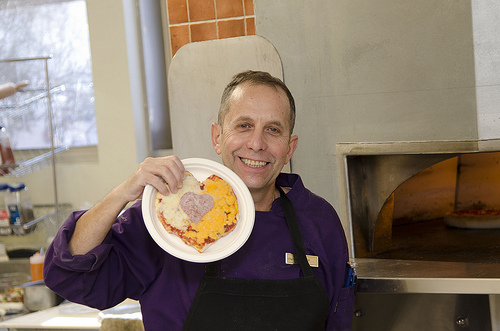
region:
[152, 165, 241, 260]
heart shaped food in middle of plate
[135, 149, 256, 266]
paper plate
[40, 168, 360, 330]
purple chefs coat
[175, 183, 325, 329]
black apron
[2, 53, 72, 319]
metal shelves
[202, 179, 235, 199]
cheese on top of food item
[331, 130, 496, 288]
painting on wall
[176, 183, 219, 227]
heart shaped slice of meat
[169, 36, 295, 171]
a rectangular pizza board behind the chef's head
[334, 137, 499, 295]
a very hot pizza oven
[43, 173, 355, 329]
a purple chef's jacket being worn by the chef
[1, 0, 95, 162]
a window on the back wall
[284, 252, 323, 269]
a white name tag on the chef's purple jacket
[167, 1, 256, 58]
tiles on the wall behind the pizza paddle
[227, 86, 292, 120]
the chef's high forehead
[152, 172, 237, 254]
a heart shaped pizza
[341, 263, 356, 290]
blue ink pens in the chef's pocket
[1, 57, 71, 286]
a medal rack for spices and rolling pins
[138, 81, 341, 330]
a man holding up a heart shaped pizza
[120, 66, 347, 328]
a man wearing a black apron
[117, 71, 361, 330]
a man holding up a plate of food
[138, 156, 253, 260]
heart shaped pizza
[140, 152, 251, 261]
heart shaped pizza with heart shaped meat in the middle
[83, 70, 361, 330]
a man wearing a gold name tag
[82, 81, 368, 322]
a man holding a heart shaped pizza on a plate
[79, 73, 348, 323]
a smiling man holding up a heart shaped pizza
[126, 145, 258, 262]
man holding a Pizza shaped like a heart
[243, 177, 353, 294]
man with a purple shirt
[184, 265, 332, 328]
man wearing a black apron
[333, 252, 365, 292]
pen on the side of the jacket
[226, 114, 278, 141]
man with blue eyes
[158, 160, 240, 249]
cheese pizza on a plate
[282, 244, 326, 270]
name tag on a shirt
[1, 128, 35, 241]
spices on the rack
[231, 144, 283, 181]
man with a smile on his face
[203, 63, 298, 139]
man with blonde hair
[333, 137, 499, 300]
a painted picture frame and art on the wall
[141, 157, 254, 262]
a plate with art glazed on it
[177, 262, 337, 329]
a black work apron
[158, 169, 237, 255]
an art design of the heart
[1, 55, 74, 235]
a metal shelf stand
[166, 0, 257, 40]
red bick on the wall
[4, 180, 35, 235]
a clear storage container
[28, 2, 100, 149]
a picture window behind the man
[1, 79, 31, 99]
a baker's roller pin